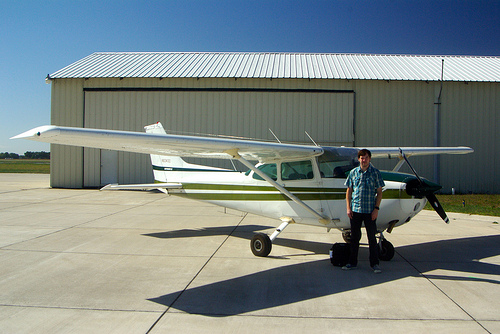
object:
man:
[340, 148, 386, 272]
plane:
[8, 119, 500, 315]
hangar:
[44, 51, 499, 190]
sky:
[0, 0, 499, 157]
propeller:
[397, 146, 450, 225]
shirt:
[344, 166, 386, 214]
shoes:
[340, 263, 357, 270]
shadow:
[138, 219, 499, 317]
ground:
[0, 173, 499, 333]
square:
[164, 257, 473, 319]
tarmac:
[0, 170, 499, 333]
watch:
[374, 205, 380, 210]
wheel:
[251, 232, 273, 256]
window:
[280, 160, 314, 181]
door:
[81, 87, 357, 187]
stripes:
[154, 182, 422, 191]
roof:
[51, 50, 499, 81]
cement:
[0, 172, 499, 333]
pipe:
[433, 84, 442, 188]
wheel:
[375, 234, 393, 261]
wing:
[9, 121, 324, 161]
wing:
[332, 144, 474, 158]